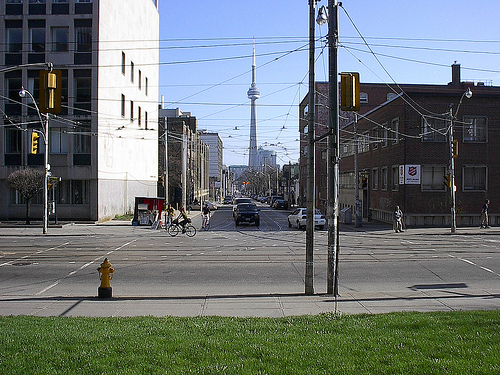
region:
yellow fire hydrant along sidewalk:
[74, 247, 125, 304]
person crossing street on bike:
[171, 205, 208, 235]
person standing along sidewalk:
[384, 204, 420, 238]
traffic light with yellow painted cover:
[23, 127, 46, 162]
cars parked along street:
[256, 182, 287, 210]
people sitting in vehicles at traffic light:
[214, 195, 267, 232]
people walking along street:
[142, 202, 172, 227]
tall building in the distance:
[224, 22, 279, 194]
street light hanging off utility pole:
[304, 2, 339, 32]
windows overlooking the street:
[118, 46, 168, 146]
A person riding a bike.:
[166, 203, 198, 239]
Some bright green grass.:
[0, 307, 499, 374]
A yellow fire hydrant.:
[96, 253, 117, 298]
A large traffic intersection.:
[0, 202, 499, 294]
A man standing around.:
[391, 205, 404, 232]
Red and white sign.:
[396, 163, 425, 185]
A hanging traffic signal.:
[30, 131, 40, 155]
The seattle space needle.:
[245, 35, 262, 167]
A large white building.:
[0, 0, 161, 220]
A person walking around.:
[477, 198, 492, 230]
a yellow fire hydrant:
[90, 252, 121, 299]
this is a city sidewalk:
[3, 292, 497, 317]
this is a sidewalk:
[4, 290, 498, 321]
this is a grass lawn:
[2, 315, 498, 370]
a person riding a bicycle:
[158, 192, 202, 241]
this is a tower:
[241, 32, 268, 202]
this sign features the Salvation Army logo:
[396, 161, 423, 183]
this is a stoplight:
[27, 124, 47, 151]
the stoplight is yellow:
[23, 124, 45, 154]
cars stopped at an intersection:
[226, 193, 262, 236]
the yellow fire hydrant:
[96, 256, 114, 298]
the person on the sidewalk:
[392, 205, 407, 233]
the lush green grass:
[0, 310, 498, 373]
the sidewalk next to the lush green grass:
[0, 290, 498, 316]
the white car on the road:
[287, 207, 326, 231]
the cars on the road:
[222, 188, 325, 232]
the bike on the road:
[167, 203, 195, 238]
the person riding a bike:
[174, 206, 189, 233]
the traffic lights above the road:
[28, 73, 459, 158]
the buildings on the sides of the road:
[2, 0, 499, 224]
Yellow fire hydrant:
[91, 253, 116, 299]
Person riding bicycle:
[165, 202, 196, 238]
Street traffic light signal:
[27, 125, 37, 152]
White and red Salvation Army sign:
[392, 160, 422, 185]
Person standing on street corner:
[365, 202, 440, 237]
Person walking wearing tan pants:
[472, 195, 492, 230]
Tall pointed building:
[241, 31, 261, 166]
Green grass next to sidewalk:
[0, 285, 496, 370]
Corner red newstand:
[125, 191, 165, 227]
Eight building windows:
[110, 46, 150, 132]